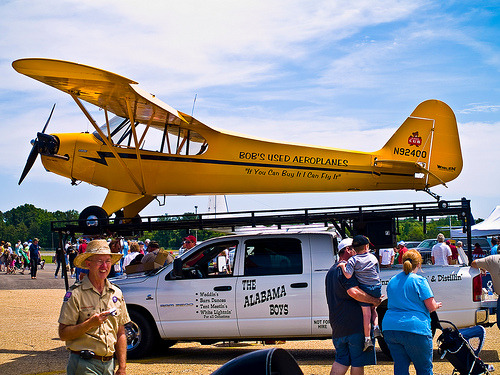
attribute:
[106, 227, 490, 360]
pick up truck — silver, large, white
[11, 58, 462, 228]
airplane — bright yellow, yellow, small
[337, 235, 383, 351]
child — little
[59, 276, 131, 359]
uniform — brown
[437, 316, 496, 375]
stroller — blue, small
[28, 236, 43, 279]
person — standing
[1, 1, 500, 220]
sky — cloudy, blue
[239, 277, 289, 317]
writing — black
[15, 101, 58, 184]
propeller — black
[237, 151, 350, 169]
writing — black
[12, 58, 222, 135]
wing — yellow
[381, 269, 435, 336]
shirt — blue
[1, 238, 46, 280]
group — large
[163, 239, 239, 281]
window — open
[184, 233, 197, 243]
hat — red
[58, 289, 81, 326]
sleeve — short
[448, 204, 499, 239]
tent — small, white